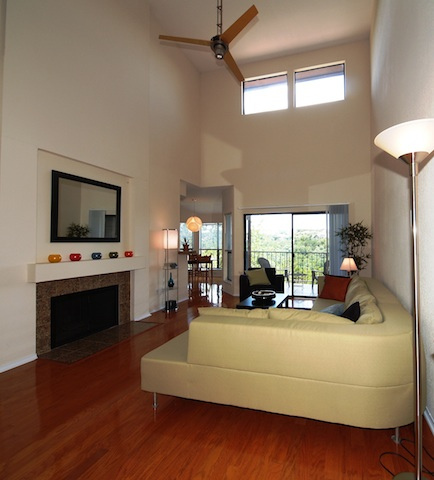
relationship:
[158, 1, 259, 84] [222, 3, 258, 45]
ceiling fan has blade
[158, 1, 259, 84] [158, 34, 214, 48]
ceiling fan has blade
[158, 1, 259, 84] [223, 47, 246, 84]
ceiling fan has blade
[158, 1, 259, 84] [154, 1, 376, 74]
ceiling fan hanging from ceiling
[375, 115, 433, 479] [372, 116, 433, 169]
floor lamp has lamp shade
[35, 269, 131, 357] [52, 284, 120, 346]
fire place has screen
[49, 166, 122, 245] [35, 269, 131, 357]
mirror hanging over fire place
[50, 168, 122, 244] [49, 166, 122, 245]
frame around mirror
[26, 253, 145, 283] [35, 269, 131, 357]
mantel above fire place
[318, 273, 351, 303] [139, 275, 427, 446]
pillow on top of sectional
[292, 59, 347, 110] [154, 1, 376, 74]
window next to ceiling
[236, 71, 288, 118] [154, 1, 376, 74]
window next to ceiling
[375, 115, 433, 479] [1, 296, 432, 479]
floor lamp on top of floor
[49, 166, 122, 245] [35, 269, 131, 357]
mirror hung above fire place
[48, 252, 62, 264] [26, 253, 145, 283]
candle on top of mantel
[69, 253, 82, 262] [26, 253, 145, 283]
candle on top of mantel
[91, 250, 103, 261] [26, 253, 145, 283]
candle on top of mantel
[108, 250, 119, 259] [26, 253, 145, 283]
candle on top of mantel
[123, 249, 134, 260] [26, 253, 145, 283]
candle on top of mantel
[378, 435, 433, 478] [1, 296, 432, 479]
cord laying on floor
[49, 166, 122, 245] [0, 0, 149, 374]
mirror hanging on wall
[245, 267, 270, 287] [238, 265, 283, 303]
pillow on top of chair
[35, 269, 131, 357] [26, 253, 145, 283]
fire place with mantel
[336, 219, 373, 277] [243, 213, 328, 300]
plant next to sliding door